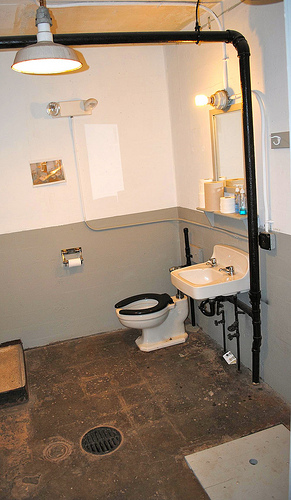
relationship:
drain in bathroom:
[77, 426, 123, 458] [1, 1, 288, 500]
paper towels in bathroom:
[201, 181, 223, 211] [1, 1, 288, 500]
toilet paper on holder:
[67, 259, 81, 267] [61, 248, 85, 269]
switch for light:
[257, 232, 275, 250] [193, 93, 211, 108]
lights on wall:
[47, 97, 99, 120] [0, 0, 289, 407]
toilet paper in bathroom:
[218, 197, 234, 213] [1, 1, 288, 500]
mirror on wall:
[209, 103, 251, 208] [0, 0, 289, 407]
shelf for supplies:
[197, 203, 249, 221] [198, 178, 249, 216]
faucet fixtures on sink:
[204, 256, 237, 275] [169, 242, 250, 302]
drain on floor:
[77, 426, 123, 458] [0, 320, 291, 499]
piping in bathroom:
[0, 29, 262, 385] [1, 1, 288, 500]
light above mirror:
[193, 93, 211, 108] [209, 103, 251, 208]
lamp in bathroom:
[10, 0, 84, 75] [1, 1, 288, 500]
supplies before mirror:
[198, 178, 249, 216] [209, 103, 251, 208]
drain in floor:
[77, 426, 123, 458] [0, 320, 291, 499]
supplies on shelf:
[198, 178, 249, 216] [197, 203, 249, 221]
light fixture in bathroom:
[193, 93, 211, 108] [1, 1, 288, 500]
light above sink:
[193, 93, 211, 108] [169, 242, 250, 302]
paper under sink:
[221, 349, 240, 367] [169, 242, 250, 302]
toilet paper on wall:
[67, 259, 81, 267] [0, 0, 289, 407]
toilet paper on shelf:
[67, 259, 81, 267] [197, 203, 249, 221]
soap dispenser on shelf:
[235, 187, 248, 216] [197, 203, 249, 221]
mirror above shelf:
[209, 103, 251, 208] [197, 203, 249, 221]